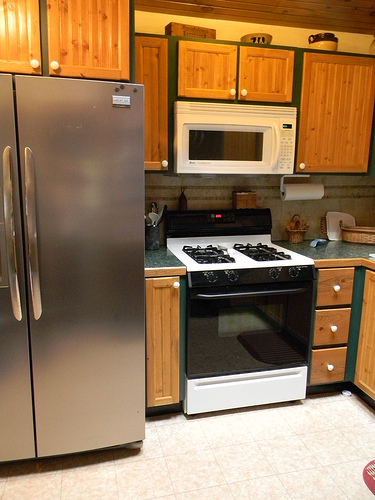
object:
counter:
[271, 238, 373, 264]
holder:
[309, 237, 326, 247]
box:
[164, 20, 216, 37]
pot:
[239, 31, 272, 46]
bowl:
[308, 32, 338, 50]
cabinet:
[298, 48, 371, 171]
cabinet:
[239, 45, 296, 102]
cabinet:
[178, 44, 236, 100]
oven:
[161, 207, 316, 415]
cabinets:
[177, 41, 296, 102]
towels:
[286, 184, 324, 202]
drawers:
[144, 267, 182, 412]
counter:
[142, 242, 187, 279]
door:
[238, 47, 294, 103]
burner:
[182, 243, 234, 265]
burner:
[233, 238, 290, 263]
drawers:
[310, 247, 355, 401]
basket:
[339, 215, 375, 247]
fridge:
[0, 71, 146, 462]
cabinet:
[133, 35, 167, 172]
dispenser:
[280, 175, 311, 195]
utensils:
[145, 200, 166, 226]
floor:
[0, 386, 372, 499]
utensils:
[285, 215, 310, 230]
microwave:
[173, 100, 299, 175]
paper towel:
[279, 184, 324, 203]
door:
[13, 73, 148, 456]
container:
[145, 224, 161, 250]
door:
[182, 278, 310, 377]